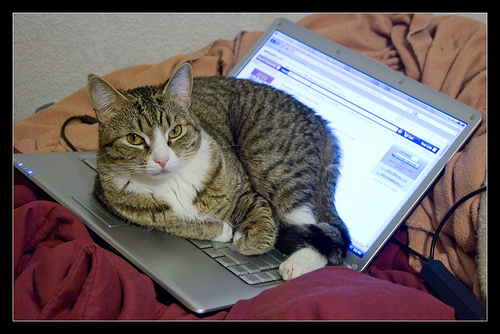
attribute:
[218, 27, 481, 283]
screen — on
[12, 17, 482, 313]
open laptop — is open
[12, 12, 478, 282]
blanket — orange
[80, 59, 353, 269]
cat — brown, big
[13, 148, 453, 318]
comforter — red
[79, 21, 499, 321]
laptop — silver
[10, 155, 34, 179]
lights — blue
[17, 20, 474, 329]
blanket — brown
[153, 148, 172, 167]
nose — pink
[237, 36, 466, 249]
image — glowing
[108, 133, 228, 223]
chest — white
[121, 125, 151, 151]
eye — green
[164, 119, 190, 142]
eye — green